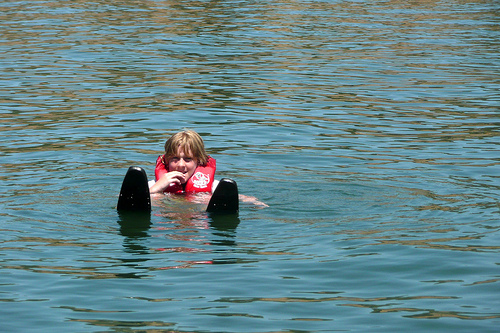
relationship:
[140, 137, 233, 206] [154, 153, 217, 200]
boy wearing life preserver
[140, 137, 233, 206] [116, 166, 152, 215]
boy wearing fins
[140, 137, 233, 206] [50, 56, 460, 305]
boy in water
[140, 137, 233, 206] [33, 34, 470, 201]
boy in lake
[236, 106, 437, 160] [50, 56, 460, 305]
ripple in water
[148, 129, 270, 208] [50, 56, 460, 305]
boy in water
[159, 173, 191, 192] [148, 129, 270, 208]
hand on boy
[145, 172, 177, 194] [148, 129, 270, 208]
arm on boy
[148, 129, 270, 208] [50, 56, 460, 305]
boy i water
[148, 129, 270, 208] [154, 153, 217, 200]
boy in life preserver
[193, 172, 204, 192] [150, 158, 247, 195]
logo on life preserver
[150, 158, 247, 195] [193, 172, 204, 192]
life preserver has logo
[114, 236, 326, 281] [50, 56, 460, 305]
reflection in water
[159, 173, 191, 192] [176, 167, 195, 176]
hand in mouth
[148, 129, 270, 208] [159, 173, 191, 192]
boy has hand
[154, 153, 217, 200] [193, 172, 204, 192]
life preserver has logo